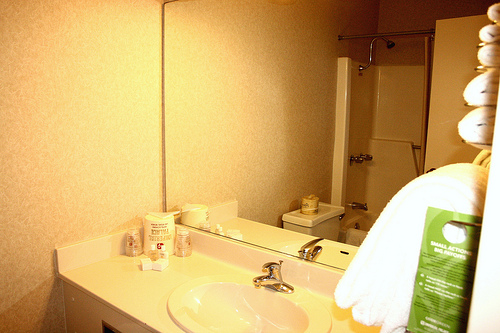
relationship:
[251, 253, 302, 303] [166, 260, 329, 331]
faucet on sink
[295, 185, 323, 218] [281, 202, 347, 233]
tissue on toilet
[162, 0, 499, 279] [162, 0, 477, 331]
mirror on wall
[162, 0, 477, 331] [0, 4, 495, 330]
wall in bath room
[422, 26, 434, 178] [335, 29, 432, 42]
shower curtain on pole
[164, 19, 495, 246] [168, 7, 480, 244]
reflection in mirror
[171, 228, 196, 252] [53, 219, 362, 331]
toiletry on counter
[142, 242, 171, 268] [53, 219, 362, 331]
toiletry on counter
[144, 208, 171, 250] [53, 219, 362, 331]
toiletry on counter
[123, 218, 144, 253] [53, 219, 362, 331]
toiletry on counter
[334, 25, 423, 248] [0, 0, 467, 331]
shower in bath room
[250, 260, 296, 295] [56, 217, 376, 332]
fixtures on sink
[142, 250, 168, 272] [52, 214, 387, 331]
small soaps on vanity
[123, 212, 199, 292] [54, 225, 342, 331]
candle on vanity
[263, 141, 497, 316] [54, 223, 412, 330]
towels to right of vanity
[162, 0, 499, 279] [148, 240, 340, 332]
mirror over sink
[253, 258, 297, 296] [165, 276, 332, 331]
faucet for sink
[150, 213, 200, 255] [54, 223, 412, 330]
cups on vanity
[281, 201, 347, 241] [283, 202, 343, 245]
toilet on toilet tank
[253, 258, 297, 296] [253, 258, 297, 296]
faucet with faucet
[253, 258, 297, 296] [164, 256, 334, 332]
faucet on sink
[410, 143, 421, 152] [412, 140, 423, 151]
end of towel bar